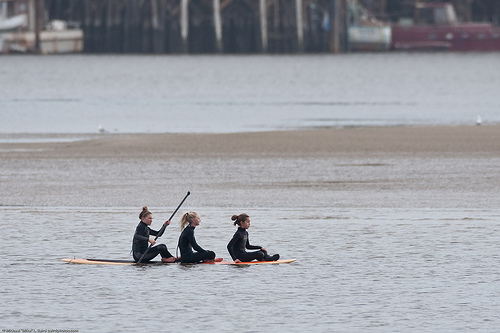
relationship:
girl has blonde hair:
[177, 211, 222, 263] [179, 211, 199, 227]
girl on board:
[226, 213, 280, 264] [57, 255, 300, 266]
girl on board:
[177, 211, 222, 263] [57, 255, 300, 266]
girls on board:
[129, 206, 177, 265] [57, 255, 300, 266]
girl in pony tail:
[226, 206, 288, 266] [227, 211, 239, 226]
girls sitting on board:
[129, 206, 177, 265] [63, 255, 295, 271]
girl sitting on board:
[177, 211, 222, 263] [56, 250, 306, 270]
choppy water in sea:
[2, 54, 498, 331] [4, 52, 499, 332]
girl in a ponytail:
[177, 211, 222, 263] [181, 212, 192, 231]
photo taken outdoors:
[12, 15, 457, 330] [0, 0, 499, 330]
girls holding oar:
[129, 206, 177, 265] [135, 192, 191, 265]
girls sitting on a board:
[129, 206, 177, 265] [51, 242, 300, 269]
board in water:
[57, 255, 301, 270] [52, 263, 457, 318]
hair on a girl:
[228, 212, 249, 226] [217, 207, 270, 265]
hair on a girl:
[175, 208, 202, 228] [163, 200, 212, 270]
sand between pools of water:
[242, 123, 392, 203] [308, 179, 478, 325]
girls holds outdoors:
[129, 206, 177, 265] [0, 0, 499, 330]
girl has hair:
[177, 211, 222, 263] [179, 210, 197, 230]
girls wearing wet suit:
[129, 210, 283, 267] [137, 221, 162, 261]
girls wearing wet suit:
[129, 210, 283, 267] [179, 225, 217, 267]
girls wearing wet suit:
[129, 210, 283, 267] [229, 228, 276, 261]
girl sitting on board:
[226, 213, 280, 264] [64, 257, 300, 267]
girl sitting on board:
[177, 211, 222, 263] [64, 257, 300, 267]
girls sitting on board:
[129, 206, 177, 265] [64, 257, 300, 267]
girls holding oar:
[129, 206, 177, 265] [146, 189, 186, 262]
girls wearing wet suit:
[129, 206, 177, 265] [179, 225, 216, 264]